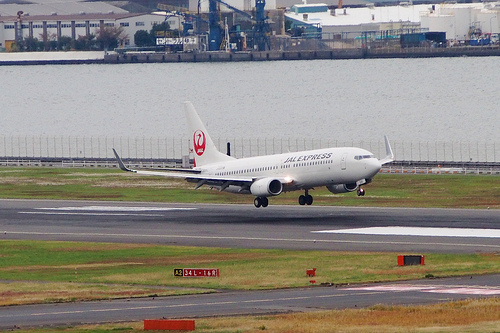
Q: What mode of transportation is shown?
A: Plane.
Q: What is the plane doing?
A: Taking off.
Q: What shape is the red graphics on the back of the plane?
A: Round.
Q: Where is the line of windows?
A: On the plane.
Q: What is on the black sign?
A: A2.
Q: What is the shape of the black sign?
A: Square.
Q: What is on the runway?
A: The airplane.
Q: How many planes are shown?
A: One.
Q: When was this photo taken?
A: During the daytime.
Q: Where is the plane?
A: On a runway.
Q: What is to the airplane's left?
A: A pond.